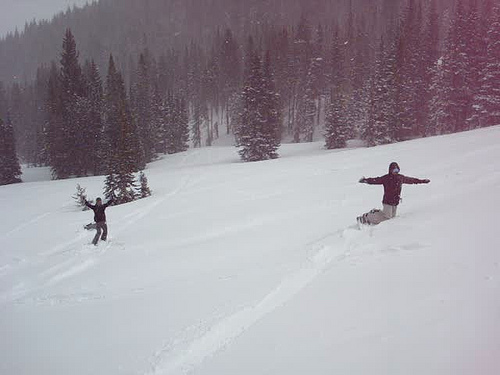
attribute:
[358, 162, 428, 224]
person — standing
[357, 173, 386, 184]
arm — outstretched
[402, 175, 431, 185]
arm — outstretched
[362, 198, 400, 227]
ski pants — khaki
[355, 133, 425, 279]
person — snowboarding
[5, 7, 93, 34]
sky — grey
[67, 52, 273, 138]
forest — hazy